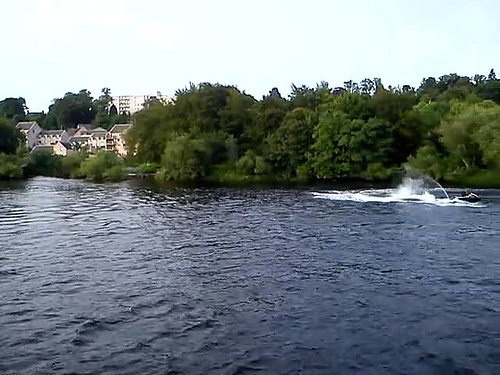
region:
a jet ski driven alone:
[441, 179, 486, 218]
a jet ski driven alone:
[427, 157, 492, 226]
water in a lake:
[46, 228, 461, 323]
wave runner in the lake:
[442, 186, 488, 208]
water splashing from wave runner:
[396, 167, 428, 194]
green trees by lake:
[174, 92, 389, 167]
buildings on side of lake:
[25, 114, 145, 161]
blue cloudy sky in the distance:
[60, 4, 427, 61]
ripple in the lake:
[77, 312, 104, 336]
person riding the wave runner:
[462, 182, 470, 199]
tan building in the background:
[109, 89, 165, 126]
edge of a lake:
[151, 174, 360, 197]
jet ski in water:
[456, 191, 478, 203]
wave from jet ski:
[316, 184, 461, 206]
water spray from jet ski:
[426, 173, 451, 201]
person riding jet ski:
[461, 186, 470, 196]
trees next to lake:
[139, 93, 494, 185]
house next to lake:
[40, 128, 70, 153]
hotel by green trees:
[110, 93, 159, 119]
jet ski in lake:
[457, 188, 482, 204]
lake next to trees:
[8, 176, 497, 372]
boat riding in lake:
[451, 189, 483, 207]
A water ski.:
[437, 180, 479, 209]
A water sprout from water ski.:
[387, 163, 451, 215]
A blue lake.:
[5, 168, 498, 363]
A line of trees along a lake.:
[139, 94, 475, 181]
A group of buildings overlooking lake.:
[17, 115, 147, 160]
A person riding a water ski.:
[455, 185, 475, 198]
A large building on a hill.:
[97, 85, 176, 116]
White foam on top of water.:
[310, 186, 412, 205]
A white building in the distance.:
[106, 94, 166, 111]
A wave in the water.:
[361, 184, 498, 196]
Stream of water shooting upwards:
[416, 172, 453, 215]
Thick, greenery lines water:
[132, 110, 492, 180]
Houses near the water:
[16, 120, 161, 160]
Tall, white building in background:
[93, 85, 164, 129]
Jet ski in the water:
[450, 182, 483, 212]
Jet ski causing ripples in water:
[309, 186, 494, 226]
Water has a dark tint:
[7, 217, 487, 355]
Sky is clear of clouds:
[6, 19, 498, 63]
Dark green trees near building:
[4, 96, 119, 122]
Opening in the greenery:
[98, 160, 190, 195]